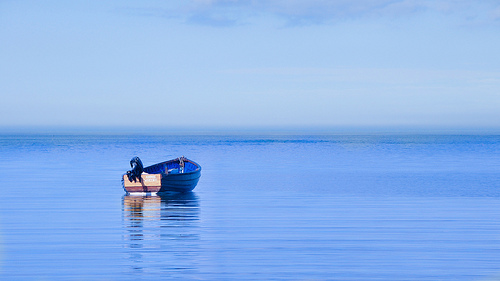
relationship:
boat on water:
[122, 156, 201, 196] [1, 139, 499, 280]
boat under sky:
[122, 156, 201, 196] [0, 0, 499, 133]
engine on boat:
[126, 156, 144, 182] [122, 156, 201, 196]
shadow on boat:
[144, 161, 197, 175] [122, 156, 201, 196]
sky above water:
[0, 0, 499, 133] [1, 139, 499, 280]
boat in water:
[122, 156, 201, 196] [1, 139, 499, 280]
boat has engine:
[122, 156, 201, 196] [126, 156, 144, 182]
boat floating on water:
[122, 156, 201, 196] [1, 139, 499, 280]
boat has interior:
[122, 156, 201, 196] [143, 161, 198, 174]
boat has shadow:
[122, 156, 201, 196] [138, 177, 151, 197]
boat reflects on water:
[122, 156, 201, 196] [1, 139, 499, 280]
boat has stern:
[122, 156, 201, 196] [124, 174, 161, 197]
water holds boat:
[1, 139, 499, 280] [122, 156, 201, 196]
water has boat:
[1, 139, 499, 280] [122, 156, 201, 196]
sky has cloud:
[0, 0, 499, 133] [71, 0, 498, 29]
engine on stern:
[126, 156, 144, 182] [124, 174, 161, 197]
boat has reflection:
[122, 156, 201, 196] [122, 191, 200, 273]